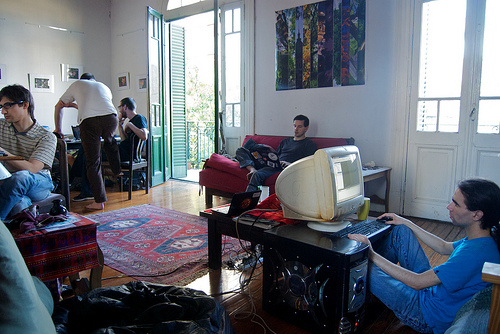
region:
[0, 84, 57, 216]
Man sitting on a wooden bench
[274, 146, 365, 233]
White monitor sitting on a table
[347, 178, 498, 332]
Man seated looking at computer monitor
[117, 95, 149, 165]
Man sitting in a chair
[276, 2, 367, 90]
Picture hanging on the wall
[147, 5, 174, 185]
Green door to room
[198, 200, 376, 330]
Dark brown wood table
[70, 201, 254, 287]
Multi-colored area rug on the floor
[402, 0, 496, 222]
White doors with long windows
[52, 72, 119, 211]
Man standing with right foot on the chair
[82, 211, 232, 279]
a red oriental rug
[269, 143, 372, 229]
a white CRT monitor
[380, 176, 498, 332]
a man wearing blue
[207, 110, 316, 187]
a man sitting on a red couch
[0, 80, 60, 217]
a man wearing glasses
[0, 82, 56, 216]
a man wearing a striped shirt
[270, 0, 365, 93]
a collage style painting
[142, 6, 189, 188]
A green door with windows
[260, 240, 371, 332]
a computer tower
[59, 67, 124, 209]
a man wearing brown pants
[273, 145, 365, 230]
A computer monitor.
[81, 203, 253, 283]
A rug on a floor.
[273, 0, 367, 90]
A poster on a wall.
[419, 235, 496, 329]
A man in a blue t-shirt.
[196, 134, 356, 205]
A red couch.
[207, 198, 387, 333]
A black table.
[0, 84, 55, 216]
A man with glasses.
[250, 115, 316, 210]
A man sitting on a couch.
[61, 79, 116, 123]
A white shirt.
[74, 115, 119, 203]
A dark pair of pants.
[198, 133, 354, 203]
the red sofa in the room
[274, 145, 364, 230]
the large computer monitor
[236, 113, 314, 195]
the man sitting on the red sofa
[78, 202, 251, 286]
the area rug on the floor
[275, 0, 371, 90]
the picture hanging on the wall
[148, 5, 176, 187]
the large door to the room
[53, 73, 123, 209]
the man standing near the door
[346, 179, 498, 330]
the man sitting in a blue shirt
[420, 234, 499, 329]
the blue short sleeved shirt on the man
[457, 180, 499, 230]
the dark hair on the man's head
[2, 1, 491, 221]
white walls of room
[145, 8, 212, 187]
front of open green door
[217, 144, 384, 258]
computer monitor on table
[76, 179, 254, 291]
rug on wood floor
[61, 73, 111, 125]
white shirt on bending body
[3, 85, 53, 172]
man in striped shirt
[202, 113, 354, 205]
man on red couch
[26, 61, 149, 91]
four framed square pictures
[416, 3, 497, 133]
glow of sunlight through windows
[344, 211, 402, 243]
two hands on keyboard